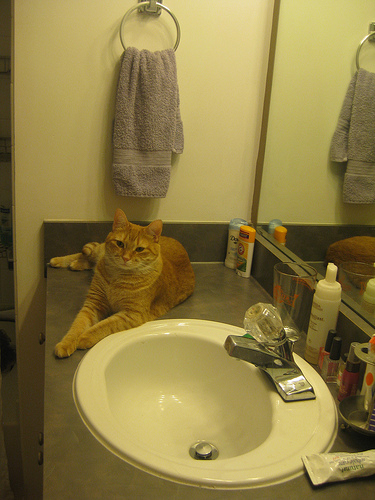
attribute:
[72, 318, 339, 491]
sink — white , round 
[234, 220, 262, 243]
cap deodorant — orange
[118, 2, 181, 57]
towel ring — metal 